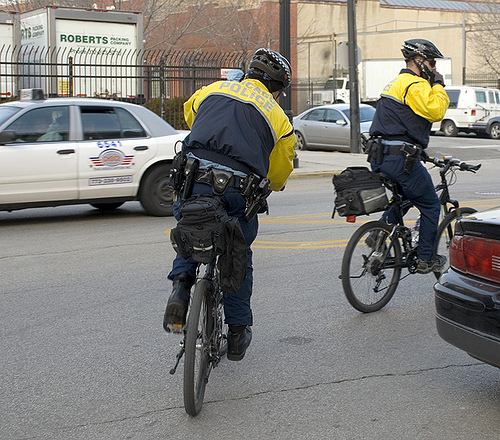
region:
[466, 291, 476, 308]
back of a car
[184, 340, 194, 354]
part of a wheel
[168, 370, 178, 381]
part of a stand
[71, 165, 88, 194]
part of a door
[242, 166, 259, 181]
part of a jacket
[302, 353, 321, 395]
edge of a road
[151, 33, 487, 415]
Two men riding bicycles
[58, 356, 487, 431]
A crack on the pavement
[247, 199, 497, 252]
Yellow lines on the street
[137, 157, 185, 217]
A black round tire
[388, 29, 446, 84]
Helmet on man's head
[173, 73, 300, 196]
Yellow and blue police jacket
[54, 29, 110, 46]
The word "ROBERTS" on a truck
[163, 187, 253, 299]
A bag on back of the bike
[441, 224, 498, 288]
A red rear light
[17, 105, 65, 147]
Driver inside the car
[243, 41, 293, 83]
His helmet is black.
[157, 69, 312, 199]
His jacket is black and yellow.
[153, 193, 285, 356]
His pants are black.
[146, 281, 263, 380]
His shoes are boots.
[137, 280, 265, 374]
His boots are black.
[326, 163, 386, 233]
The pack is black.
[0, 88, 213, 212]
The car is white.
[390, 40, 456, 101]
He is talking on the radio.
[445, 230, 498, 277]
The light is red.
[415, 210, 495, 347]
The car is black.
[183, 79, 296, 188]
yellow and black jacket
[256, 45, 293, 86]
black and white helmet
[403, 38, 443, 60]
bike helmet on head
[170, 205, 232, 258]
black bag on bike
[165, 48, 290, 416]
man riding on bike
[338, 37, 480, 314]
police officer on bike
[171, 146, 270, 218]
utility belt on waist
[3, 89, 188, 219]
grey and white car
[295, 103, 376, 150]
grey car by curb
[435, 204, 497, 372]
black car by curb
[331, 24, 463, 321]
person riding a bike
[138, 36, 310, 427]
a police officer riding a bike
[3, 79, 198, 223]
a white car in the road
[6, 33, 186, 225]
a fence in front a white car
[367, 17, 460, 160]
person holds a phone in his right hand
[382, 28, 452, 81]
a black helmet on head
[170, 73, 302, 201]
a yellow and blue jacket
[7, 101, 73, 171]
a driver inside a car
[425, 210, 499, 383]
a red tail light of a car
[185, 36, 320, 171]
police officer wears a helmet